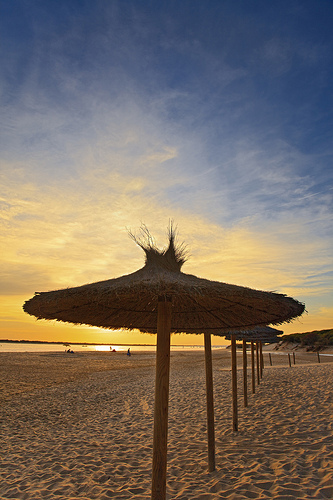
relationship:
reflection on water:
[93, 344, 120, 350] [0, 342, 225, 351]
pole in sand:
[198, 333, 221, 474] [253, 382, 317, 468]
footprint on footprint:
[47, 482, 61, 490] [253, 481, 271, 491]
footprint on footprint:
[47, 482, 61, 490] [76, 454, 95, 461]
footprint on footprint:
[47, 482, 61, 490] [277, 483, 302, 490]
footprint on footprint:
[47, 482, 61, 490] [0, 488, 16, 498]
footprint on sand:
[47, 482, 61, 490] [1, 350, 329, 496]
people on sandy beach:
[64, 344, 132, 357] [27, 345, 315, 495]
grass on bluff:
[276, 328, 332, 350] [256, 325, 332, 353]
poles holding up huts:
[125, 340, 294, 437] [32, 234, 298, 498]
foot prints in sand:
[223, 438, 327, 497] [4, 335, 330, 498]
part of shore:
[67, 413, 146, 491] [18, 345, 260, 427]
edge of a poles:
[149, 414, 157, 443] [151, 303, 174, 496]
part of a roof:
[116, 286, 135, 315] [188, 301, 207, 311]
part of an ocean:
[9, 340, 21, 346] [1, 340, 229, 358]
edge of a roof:
[54, 283, 276, 303] [46, 284, 246, 294]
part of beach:
[88, 432, 129, 480] [18, 363, 143, 460]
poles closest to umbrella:
[151, 303, 174, 496] [16, 214, 321, 499]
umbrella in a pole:
[16, 214, 321, 499] [150, 299, 174, 499]